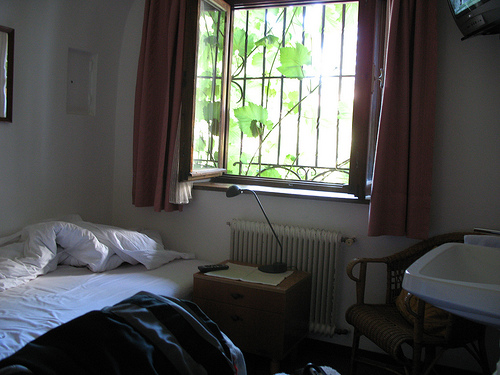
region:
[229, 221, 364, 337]
metal radiator is white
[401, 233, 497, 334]
sink against wall is white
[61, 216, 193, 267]
white pillow on bed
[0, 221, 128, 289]
white blanket on bed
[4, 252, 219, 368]
white sheet on bed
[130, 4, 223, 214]
brown curtain is hanging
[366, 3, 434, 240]
brown curtain is hanging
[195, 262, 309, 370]
brown table next to bed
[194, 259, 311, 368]
brown table under window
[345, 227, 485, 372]
wooden chair next to sink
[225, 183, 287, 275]
a metal table lamp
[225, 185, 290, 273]
a metal reading lamp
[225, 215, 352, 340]
a white steel radiator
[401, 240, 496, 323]
a white porcelain sink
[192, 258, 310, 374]
a wooden bedside table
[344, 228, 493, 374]
a brown wicker chair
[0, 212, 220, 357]
an unkempt bed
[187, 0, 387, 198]
an iron bar covered window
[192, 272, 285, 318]
a brown wooden drawer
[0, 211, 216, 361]
a wrinkled white sheet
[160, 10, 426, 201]
tbars are on the window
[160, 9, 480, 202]
the window is open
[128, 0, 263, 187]
brown curtains are on the window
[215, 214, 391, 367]
the heater is on the wall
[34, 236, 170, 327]
the bed is unmade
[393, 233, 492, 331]
the white sink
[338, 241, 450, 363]
the chair is in the corner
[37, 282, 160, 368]
the blanket is next to the bed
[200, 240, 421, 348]
the table is nex to the bed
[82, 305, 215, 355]
a blue blanket is by the bed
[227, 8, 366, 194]
back metal bars in window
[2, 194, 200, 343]
unmade white bed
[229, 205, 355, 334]
old white painted heater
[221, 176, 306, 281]
skinny black task lamp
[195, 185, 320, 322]
lamp and remote on night stand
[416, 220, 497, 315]
white porcelain sink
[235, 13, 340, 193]
large green leaves outside window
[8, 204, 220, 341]
white sheets and comforter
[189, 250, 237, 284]
black remote control on night stand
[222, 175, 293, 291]
black task lamp on night stand